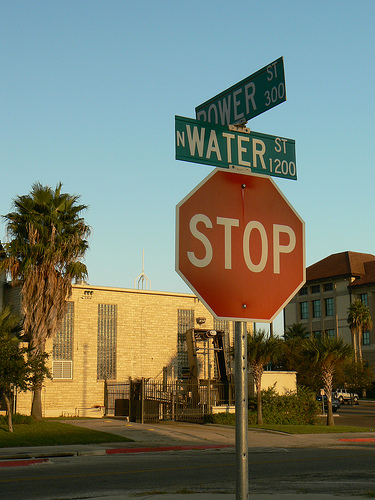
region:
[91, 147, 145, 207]
part of the sky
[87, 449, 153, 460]
edge of a road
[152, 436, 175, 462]
edge of a road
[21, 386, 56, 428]
part of a house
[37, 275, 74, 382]
part of a window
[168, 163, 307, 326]
the red STOP sign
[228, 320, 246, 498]
the silver pole for the sign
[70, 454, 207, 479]
the yellow lines on the road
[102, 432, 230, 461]
the red paint on the curb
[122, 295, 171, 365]
the light brick building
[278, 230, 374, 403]
the tall building on the right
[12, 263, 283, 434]
the short building on the left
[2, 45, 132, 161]
the clear blue sky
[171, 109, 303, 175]
the street signs that says WATER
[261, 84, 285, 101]
the 300 on the street sign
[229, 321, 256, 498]
the pole for the STOP sign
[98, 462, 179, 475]
the yellow lines on the road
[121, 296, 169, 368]
the brick building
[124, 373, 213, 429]
the black gate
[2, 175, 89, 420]
the tall palm tree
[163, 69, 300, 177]
the green street signs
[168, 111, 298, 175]
the street sign that says WATER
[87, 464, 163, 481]
Road with tarmac in the photo.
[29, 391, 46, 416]
A tree trunk in the photo.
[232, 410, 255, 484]
A metal pole in the photo.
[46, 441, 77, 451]
A paved sidewalk in the picture.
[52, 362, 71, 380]
A window in the photo.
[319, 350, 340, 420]
A tree in the picture.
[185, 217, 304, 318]
A Stop sign in the picture.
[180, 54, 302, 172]
Signages giving directions in the picture.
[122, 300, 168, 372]
A building in the picture.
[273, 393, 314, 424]
A hedge in the photo.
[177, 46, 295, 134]
green street sign reading power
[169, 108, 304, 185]
green street sign reading water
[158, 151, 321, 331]
large red stop sign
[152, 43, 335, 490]
street signs on a pole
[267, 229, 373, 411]
large building with red roof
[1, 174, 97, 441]
very tall palm tree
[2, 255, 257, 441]
building made of white brick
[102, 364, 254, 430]
small rod iron fence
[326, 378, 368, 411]
small silver sport utility vehicle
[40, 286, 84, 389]
white air vent in window